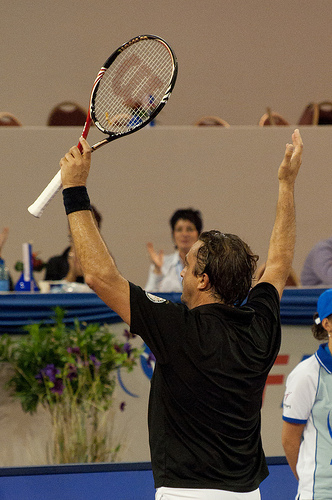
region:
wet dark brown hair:
[205, 248, 246, 278]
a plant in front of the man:
[22, 330, 120, 458]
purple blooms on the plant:
[40, 360, 69, 389]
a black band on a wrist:
[60, 184, 93, 218]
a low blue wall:
[9, 467, 150, 498]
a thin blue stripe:
[314, 427, 316, 494]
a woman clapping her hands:
[151, 200, 192, 292]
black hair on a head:
[177, 207, 196, 216]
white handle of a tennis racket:
[37, 190, 55, 204]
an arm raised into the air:
[260, 122, 302, 317]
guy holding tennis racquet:
[25, 20, 324, 444]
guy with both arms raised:
[23, 130, 329, 387]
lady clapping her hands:
[116, 187, 201, 309]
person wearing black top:
[1, 193, 137, 332]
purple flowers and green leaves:
[11, 323, 159, 441]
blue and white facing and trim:
[8, 277, 140, 494]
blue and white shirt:
[271, 319, 330, 495]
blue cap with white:
[310, 284, 330, 337]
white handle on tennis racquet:
[18, 27, 173, 233]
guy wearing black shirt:
[104, 218, 287, 499]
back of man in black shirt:
[124, 233, 289, 489]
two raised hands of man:
[60, 126, 308, 319]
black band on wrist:
[59, 140, 95, 216]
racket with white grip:
[28, 31, 177, 216]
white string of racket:
[94, 42, 167, 131]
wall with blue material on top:
[1, 288, 324, 460]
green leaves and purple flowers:
[14, 321, 132, 412]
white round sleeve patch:
[141, 290, 167, 304]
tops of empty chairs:
[2, 100, 330, 128]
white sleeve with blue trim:
[282, 354, 321, 423]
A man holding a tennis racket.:
[12, 28, 180, 225]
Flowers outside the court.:
[4, 308, 115, 422]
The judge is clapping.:
[131, 199, 227, 286]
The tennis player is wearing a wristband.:
[29, 167, 115, 223]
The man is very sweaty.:
[138, 221, 273, 308]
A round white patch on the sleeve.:
[101, 288, 185, 322]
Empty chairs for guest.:
[181, 94, 323, 131]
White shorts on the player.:
[116, 468, 279, 498]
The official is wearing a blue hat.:
[310, 286, 327, 335]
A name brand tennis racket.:
[55, 11, 221, 146]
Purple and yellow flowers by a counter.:
[35, 344, 107, 461]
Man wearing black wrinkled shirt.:
[128, 228, 280, 494]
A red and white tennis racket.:
[24, 21, 180, 220]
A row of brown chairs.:
[3, 98, 331, 127]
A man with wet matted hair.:
[178, 228, 260, 311]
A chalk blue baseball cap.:
[316, 287, 330, 327]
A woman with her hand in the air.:
[146, 206, 204, 291]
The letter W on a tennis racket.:
[109, 54, 163, 110]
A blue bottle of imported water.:
[16, 243, 41, 291]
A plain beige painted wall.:
[5, 4, 327, 31]